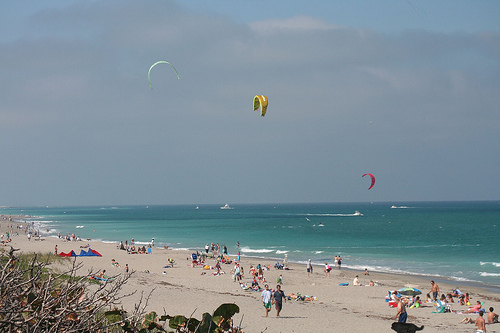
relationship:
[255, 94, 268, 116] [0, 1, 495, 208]
kite in sky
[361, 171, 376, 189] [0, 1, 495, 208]
kite in sky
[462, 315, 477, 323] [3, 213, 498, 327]
person on beach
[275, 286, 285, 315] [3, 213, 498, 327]
person on beach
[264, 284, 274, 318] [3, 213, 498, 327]
person on beach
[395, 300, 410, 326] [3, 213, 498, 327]
person on beach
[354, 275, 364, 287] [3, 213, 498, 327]
person on beach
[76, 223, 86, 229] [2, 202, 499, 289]
wave in sea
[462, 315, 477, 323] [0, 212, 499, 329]
person on ground